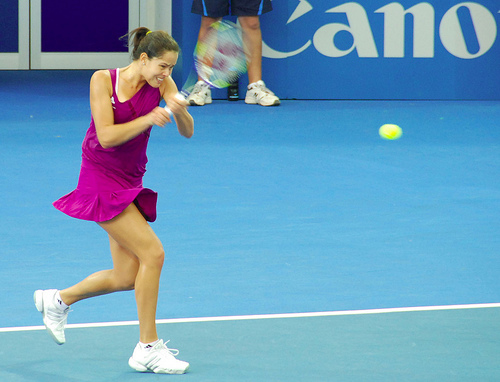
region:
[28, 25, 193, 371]
the woman playing tennis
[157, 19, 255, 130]
the racquet in the woman's hands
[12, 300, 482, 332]
the white line on the court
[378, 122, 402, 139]
the ball in mid air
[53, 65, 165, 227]
the woman's purple outfit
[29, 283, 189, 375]
the white shoes on the woman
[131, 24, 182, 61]
the hair on the woman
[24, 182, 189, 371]
the two legs on the woman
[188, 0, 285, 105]
the legs of a person standing in the back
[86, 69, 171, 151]
the woman's right arm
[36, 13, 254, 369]
woman on tennis court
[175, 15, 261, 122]
blur of moving racket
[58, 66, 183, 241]
purple outfit on woman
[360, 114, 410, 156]
yellow ball in mid air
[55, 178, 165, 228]
skirt of player's outfit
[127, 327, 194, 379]
white sneaker on court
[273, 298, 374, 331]
white line on court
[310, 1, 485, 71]
white letters on blue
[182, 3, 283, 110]
person standing against wall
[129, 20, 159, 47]
brown hair in ponytail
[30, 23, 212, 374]
Woman playing tennis.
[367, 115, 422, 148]
Tennis ball in air.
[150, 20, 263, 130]
Blurred tennis racket.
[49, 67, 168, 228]
Tennis player's pink dress.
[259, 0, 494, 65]
White letters on blue sign.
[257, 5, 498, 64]
Letters Cano on sign.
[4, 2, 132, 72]
Silver and blue doors.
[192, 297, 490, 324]
White line on tennis court.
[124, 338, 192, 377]
Tennis player's white shoe.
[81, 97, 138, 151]
Tennis player's bent right elbow.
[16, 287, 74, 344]
White tied sneaker sport shoe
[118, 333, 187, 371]
White tied sneaker sport shoe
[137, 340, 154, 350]
White Adidas ankle socks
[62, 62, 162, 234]
A short Maroon dress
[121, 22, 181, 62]
Neatly tied hair with yellow band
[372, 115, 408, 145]
A yellow tennis ball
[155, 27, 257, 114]
A multi coloured tennis racket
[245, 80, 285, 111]
White tied sneaker sport shoe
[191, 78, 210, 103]
White tied sneaker sport shoe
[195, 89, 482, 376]
A well marked tennis court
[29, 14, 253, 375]
a woman playing tennis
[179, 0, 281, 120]
a person watching the tennis game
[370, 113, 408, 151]
yellow tennis ball in the air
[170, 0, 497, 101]
wall surrounding the tennis court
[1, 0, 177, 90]
doors leading to the tennis court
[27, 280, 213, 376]
white tennis shoes on the woman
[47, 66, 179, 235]
purple dress on the woman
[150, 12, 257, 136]
blue and yellow tennis racket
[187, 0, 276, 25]
black and blue shorts on the man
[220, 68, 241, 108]
bottle of water under the person